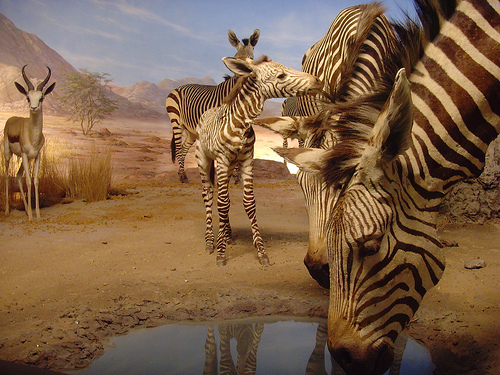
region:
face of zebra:
[233, 46, 328, 112]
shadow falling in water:
[188, 322, 270, 372]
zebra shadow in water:
[206, 322, 329, 373]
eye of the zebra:
[353, 222, 395, 277]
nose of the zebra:
[312, 338, 355, 373]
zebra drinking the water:
[272, 193, 402, 373]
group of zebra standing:
[123, 31, 496, 316]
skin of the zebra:
[213, 124, 234, 145]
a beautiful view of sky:
[50, 17, 497, 203]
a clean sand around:
[28, 205, 498, 372]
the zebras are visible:
[179, 76, 418, 331]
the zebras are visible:
[244, 96, 375, 359]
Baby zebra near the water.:
[169, 52, 324, 272]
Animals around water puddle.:
[145, 13, 475, 373]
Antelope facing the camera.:
[4, 53, 60, 220]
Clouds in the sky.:
[58, 4, 181, 67]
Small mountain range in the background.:
[3, 15, 221, 129]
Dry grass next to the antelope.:
[53, 154, 114, 199]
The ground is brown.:
[33, 237, 163, 298]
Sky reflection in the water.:
[275, 330, 308, 373]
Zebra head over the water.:
[281, 162, 445, 374]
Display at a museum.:
[10, 0, 499, 372]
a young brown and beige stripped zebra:
[196, 55, 314, 254]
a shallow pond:
[55, 295, 448, 372]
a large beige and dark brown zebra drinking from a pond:
[323, 3, 497, 373]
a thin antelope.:
[1, 65, 56, 227]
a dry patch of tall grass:
[46, 153, 111, 209]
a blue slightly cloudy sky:
[3, 0, 380, 91]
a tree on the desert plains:
[61, 73, 112, 145]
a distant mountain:
[0, 10, 170, 120]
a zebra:
[166, 30, 263, 180]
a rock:
[466, 256, 491, 273]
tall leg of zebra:
[214, 220, 234, 267]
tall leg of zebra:
[240, 212, 268, 264]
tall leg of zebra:
[200, 211, 215, 252]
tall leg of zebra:
[229, 224, 233, 246]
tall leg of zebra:
[173, 154, 188, 187]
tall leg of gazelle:
[26, 177, 35, 222]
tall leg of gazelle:
[33, 182, 48, 218]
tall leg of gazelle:
[1, 185, 14, 220]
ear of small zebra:
[216, 54, 257, 81]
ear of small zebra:
[223, 25, 243, 47]